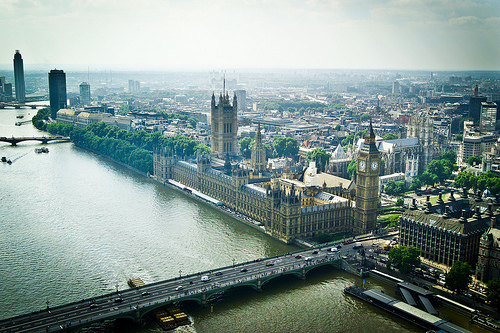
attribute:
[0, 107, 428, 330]
water — body, calm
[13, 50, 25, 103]
building — tall, big, large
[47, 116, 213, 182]
trees — green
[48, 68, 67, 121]
tower — large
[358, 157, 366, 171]
clock — white, big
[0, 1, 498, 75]
sky — gray, cloudy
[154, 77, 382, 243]
castle — large